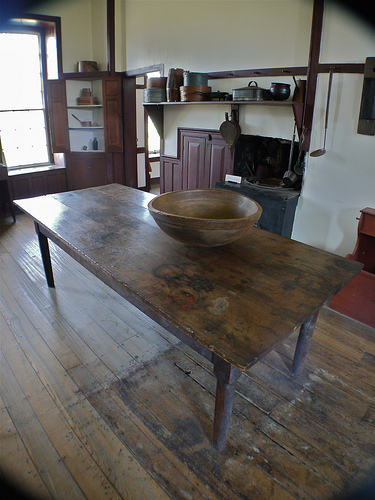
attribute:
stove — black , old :
[215, 125, 306, 240]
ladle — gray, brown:
[308, 68, 332, 157]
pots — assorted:
[135, 62, 305, 107]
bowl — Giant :
[149, 186, 262, 247]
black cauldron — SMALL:
[268, 79, 287, 101]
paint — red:
[179, 293, 196, 310]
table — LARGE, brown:
[7, 162, 372, 460]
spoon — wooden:
[302, 64, 337, 160]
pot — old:
[77, 60, 97, 72]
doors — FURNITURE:
[43, 70, 127, 185]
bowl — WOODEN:
[137, 160, 273, 245]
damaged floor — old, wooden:
[95, 327, 371, 493]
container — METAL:
[218, 79, 269, 102]